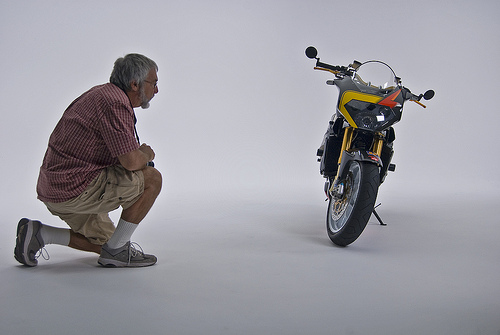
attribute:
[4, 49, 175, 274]
man — plaid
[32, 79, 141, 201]
shirt — red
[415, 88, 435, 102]
mirror — rear view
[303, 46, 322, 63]
mirror — rear view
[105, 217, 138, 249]
sock — long, white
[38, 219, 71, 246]
sock — white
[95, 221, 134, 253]
sock — white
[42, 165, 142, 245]
shorts — tan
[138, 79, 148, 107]
beard — salt and pepper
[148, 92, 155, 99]
mustache — salt and pepper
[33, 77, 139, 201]
checkered shirt — red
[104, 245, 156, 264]
shoe — gray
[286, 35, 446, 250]
motorcycle — yellow , red 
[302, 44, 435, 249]
bike — red, yellow